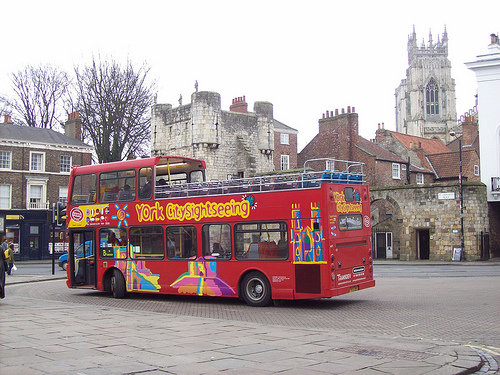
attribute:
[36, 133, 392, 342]
bus — red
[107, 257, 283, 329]
tires — black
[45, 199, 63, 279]
traffic light — black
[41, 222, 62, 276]
pole — black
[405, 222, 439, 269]
door — black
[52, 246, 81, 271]
car — blue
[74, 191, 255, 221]
sign — colorful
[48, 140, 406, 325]
bus — red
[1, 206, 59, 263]
front door — black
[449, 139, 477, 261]
pole — tall, black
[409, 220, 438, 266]
door — black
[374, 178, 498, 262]
building — brick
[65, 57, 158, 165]
tree — leafless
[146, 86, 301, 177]
building — old, white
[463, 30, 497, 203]
building — white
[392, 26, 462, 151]
tower — gothic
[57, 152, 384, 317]
bus — red, double decker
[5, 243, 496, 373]
street — stoned, paved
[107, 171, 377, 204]
seats — blue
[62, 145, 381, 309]
bus — colorful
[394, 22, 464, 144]
tower — gothic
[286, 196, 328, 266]
castle — colorful